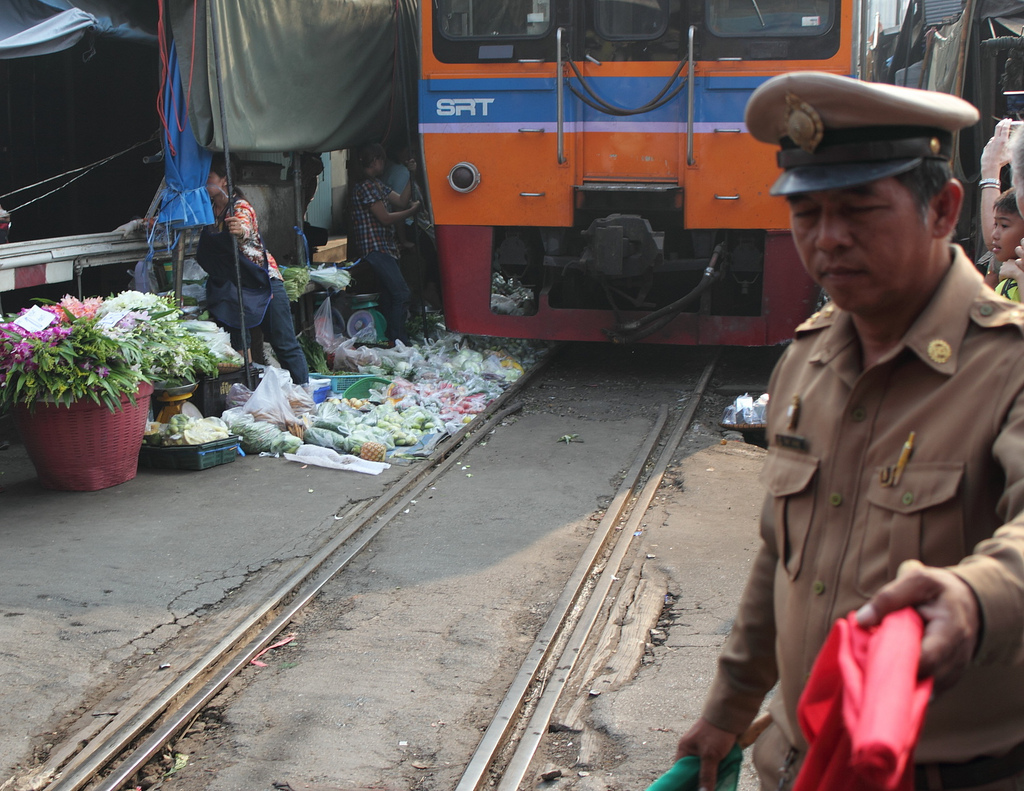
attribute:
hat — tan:
[727, 62, 980, 202]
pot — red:
[18, 387, 161, 496]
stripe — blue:
[407, 75, 791, 120]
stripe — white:
[417, 116, 766, 139]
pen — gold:
[894, 429, 924, 465]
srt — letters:
[414, 84, 517, 127]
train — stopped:
[384, 6, 898, 361]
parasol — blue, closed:
[140, 18, 277, 304]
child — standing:
[971, 169, 1017, 324]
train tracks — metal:
[300, 375, 711, 573]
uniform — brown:
[736, 75, 1019, 532]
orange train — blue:
[415, 29, 873, 321]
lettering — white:
[432, 87, 498, 131]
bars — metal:
[501, 238, 741, 293]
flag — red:
[790, 601, 942, 787]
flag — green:
[660, 757, 734, 786]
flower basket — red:
[34, 381, 149, 485]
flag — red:
[790, 593, 931, 786]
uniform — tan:
[682, 243, 1020, 760]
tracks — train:
[66, 352, 753, 787]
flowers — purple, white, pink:
[2, 293, 231, 447]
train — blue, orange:
[399, 15, 994, 419]